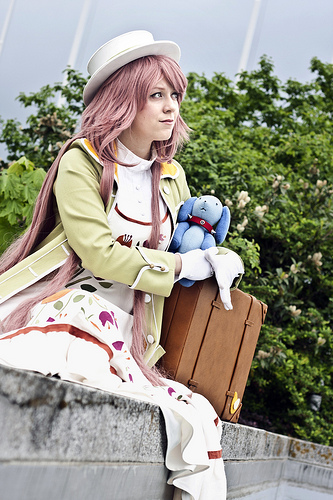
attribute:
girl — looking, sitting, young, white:
[21, 31, 265, 409]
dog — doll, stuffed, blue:
[170, 185, 225, 265]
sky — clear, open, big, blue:
[2, 4, 330, 83]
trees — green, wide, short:
[6, 79, 330, 422]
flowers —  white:
[234, 189, 252, 212]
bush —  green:
[185, 55, 330, 443]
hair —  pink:
[79, 57, 154, 164]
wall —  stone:
[4, 365, 331, 493]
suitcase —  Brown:
[158, 290, 267, 421]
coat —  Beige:
[0, 141, 189, 367]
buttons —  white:
[144, 334, 154, 343]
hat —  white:
[82, 29, 180, 100]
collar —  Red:
[186, 213, 216, 236]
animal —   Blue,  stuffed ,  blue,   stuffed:
[170, 192, 230, 285]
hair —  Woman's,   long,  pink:
[79, 64, 155, 148]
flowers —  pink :
[98, 309, 120, 328]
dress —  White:
[2, 135, 226, 498]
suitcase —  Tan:
[162, 278, 268, 418]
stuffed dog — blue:
[176, 193, 231, 272]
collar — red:
[183, 210, 219, 233]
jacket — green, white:
[21, 124, 203, 365]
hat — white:
[75, 27, 184, 92]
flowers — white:
[231, 188, 251, 204]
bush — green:
[35, 78, 330, 416]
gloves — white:
[174, 243, 246, 299]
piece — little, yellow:
[228, 392, 243, 422]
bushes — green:
[14, 61, 330, 380]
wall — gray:
[12, 379, 315, 487]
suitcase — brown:
[159, 257, 257, 431]